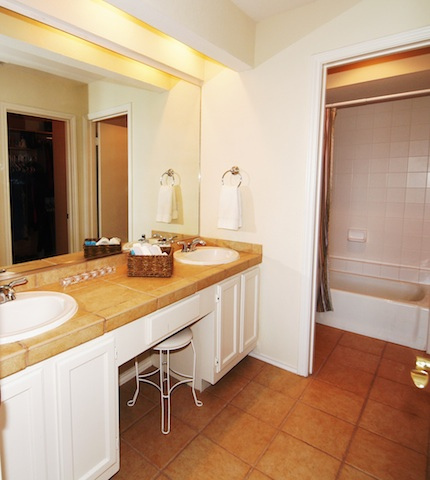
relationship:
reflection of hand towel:
[343, 159, 428, 200] [215, 186, 243, 231]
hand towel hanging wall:
[215, 186, 243, 233] [201, 78, 365, 224]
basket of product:
[127, 242, 174, 277] [130, 242, 144, 253]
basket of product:
[127, 242, 174, 277] [139, 240, 157, 255]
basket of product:
[127, 242, 174, 277] [153, 241, 160, 255]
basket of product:
[127, 242, 174, 277] [160, 249, 168, 256]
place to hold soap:
[346, 226, 368, 244] [347, 229, 367, 241]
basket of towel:
[124, 242, 174, 279] [150, 243, 162, 255]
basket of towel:
[124, 242, 174, 279] [139, 241, 154, 255]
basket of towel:
[124, 242, 174, 279] [130, 241, 147, 254]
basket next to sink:
[124, 242, 174, 279] [169, 236, 240, 268]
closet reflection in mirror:
[5, 108, 79, 266] [1, 8, 201, 281]